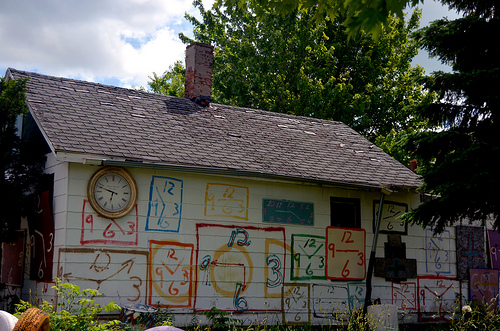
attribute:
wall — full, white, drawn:
[70, 161, 496, 319]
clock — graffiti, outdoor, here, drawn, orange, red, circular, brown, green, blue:
[91, 159, 149, 215]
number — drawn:
[341, 231, 359, 247]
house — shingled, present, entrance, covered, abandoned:
[4, 65, 446, 322]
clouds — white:
[0, 1, 199, 103]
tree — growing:
[151, 2, 434, 144]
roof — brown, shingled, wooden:
[10, 65, 421, 186]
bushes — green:
[36, 277, 120, 330]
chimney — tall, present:
[175, 37, 226, 105]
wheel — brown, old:
[17, 305, 47, 328]